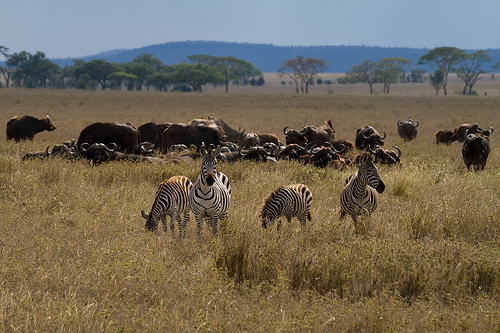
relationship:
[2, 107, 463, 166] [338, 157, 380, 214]
bull behind zebra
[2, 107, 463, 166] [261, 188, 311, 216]
bull behind zebra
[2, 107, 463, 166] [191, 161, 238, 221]
bull behind zebra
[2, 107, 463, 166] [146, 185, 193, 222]
bull behind zebra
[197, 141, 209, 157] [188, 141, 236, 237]
white ear on animal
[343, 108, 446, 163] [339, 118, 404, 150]
animal has horns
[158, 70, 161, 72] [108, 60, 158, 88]
leaf on tree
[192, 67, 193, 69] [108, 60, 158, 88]
leaf on tree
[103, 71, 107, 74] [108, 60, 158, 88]
leaf on tree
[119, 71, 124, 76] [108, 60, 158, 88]
leaf on tree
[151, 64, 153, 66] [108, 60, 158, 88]
leaf on tree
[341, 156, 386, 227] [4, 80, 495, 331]
animal in field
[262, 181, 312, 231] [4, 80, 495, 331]
animal in field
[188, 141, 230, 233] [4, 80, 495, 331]
animal in field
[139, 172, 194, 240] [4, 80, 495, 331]
animals in field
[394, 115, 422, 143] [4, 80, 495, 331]
animal in field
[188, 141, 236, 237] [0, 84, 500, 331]
animal in grass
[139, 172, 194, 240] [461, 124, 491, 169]
animals with buffalo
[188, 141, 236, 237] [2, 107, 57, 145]
animal with bull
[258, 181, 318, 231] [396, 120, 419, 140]
animal with buffalo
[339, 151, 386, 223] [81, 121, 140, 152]
animal with buffalo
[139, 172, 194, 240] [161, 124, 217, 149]
animals with buffalo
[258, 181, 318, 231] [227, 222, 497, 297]
animal in grass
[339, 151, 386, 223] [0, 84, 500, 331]
animal in grass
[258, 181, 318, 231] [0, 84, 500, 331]
animal in grass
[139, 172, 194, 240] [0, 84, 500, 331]
animals in grass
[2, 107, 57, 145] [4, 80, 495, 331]
bull in field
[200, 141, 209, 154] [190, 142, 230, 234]
white ear on zebra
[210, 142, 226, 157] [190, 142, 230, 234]
white ear on zebra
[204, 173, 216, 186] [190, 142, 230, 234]
black nose on zebra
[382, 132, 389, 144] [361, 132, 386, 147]
horns on head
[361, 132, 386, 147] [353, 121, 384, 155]
head on water buffalo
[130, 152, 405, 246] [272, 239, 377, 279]
animals in grass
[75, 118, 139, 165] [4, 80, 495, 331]
bull in field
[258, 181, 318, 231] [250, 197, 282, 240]
animal has head